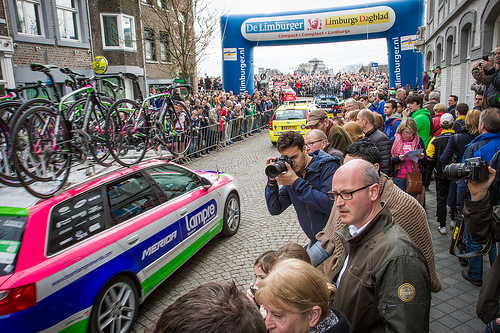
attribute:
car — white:
[6, 140, 253, 319]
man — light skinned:
[319, 162, 407, 269]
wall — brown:
[135, 6, 167, 27]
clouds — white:
[251, 43, 387, 64]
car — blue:
[261, 79, 333, 164]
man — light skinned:
[329, 159, 433, 330]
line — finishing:
[220, 10, 427, 85]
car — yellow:
[267, 107, 311, 142]